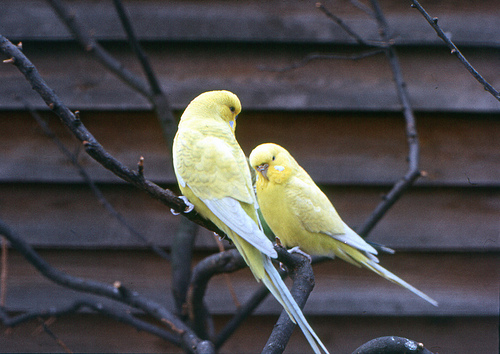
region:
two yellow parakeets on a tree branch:
[140, 80, 442, 352]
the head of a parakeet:
[191, 81, 249, 133]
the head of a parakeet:
[248, 138, 295, 189]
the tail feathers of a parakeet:
[360, 249, 450, 313]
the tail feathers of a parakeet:
[266, 269, 328, 351]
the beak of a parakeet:
[254, 165, 272, 181]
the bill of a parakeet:
[256, 163, 270, 183]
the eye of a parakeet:
[267, 150, 282, 164]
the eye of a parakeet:
[220, 98, 240, 120]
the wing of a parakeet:
[293, 171, 377, 255]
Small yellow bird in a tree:
[163, 74, 269, 298]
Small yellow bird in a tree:
[249, 125, 410, 297]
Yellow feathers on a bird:
[172, 122, 193, 153]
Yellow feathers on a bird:
[177, 165, 195, 190]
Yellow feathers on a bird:
[198, 184, 218, 199]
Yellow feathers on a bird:
[211, 161, 225, 185]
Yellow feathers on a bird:
[187, 147, 204, 176]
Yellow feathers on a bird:
[205, 141, 225, 166]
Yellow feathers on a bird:
[280, 197, 309, 223]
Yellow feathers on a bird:
[312, 228, 327, 256]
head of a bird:
[196, 75, 266, 130]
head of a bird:
[245, 133, 305, 193]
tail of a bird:
[222, 197, 299, 292]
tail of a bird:
[327, 218, 444, 290]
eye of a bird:
[225, 94, 248, 111]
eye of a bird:
[262, 142, 289, 165]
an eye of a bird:
[215, 95, 247, 115]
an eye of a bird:
[269, 146, 283, 166]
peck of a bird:
[257, 160, 272, 183]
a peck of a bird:
[257, 163, 276, 190]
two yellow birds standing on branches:
[170, 87, 437, 349]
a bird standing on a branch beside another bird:
[250, 143, 443, 308]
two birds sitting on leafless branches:
[0, 0, 498, 352]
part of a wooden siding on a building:
[165, 4, 255, 87]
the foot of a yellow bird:
[168, 194, 195, 217]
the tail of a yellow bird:
[257, 258, 330, 352]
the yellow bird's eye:
[226, 102, 238, 116]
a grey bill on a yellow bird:
[250, 160, 273, 181]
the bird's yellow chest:
[258, 180, 275, 217]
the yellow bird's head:
[212, 89, 241, 119]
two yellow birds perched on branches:
[167, 88, 444, 343]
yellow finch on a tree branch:
[172, 82, 327, 352]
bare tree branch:
[2, 0, 497, 352]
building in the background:
[6, 8, 496, 351]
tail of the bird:
[359, 231, 441, 311]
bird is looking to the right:
[179, 83, 240, 136]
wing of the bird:
[175, 141, 279, 257]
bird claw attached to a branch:
[168, 189, 197, 218]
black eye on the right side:
[227, 103, 237, 116]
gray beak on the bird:
[255, 158, 271, 185]